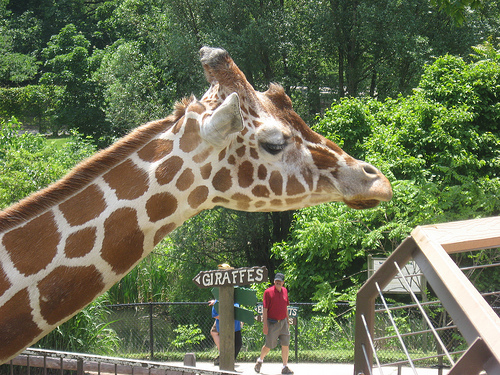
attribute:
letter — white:
[202, 267, 235, 292]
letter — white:
[210, 268, 229, 295]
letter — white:
[209, 261, 246, 291]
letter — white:
[228, 267, 252, 300]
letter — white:
[240, 259, 275, 287]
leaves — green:
[54, 24, 497, 284]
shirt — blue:
[211, 287, 243, 322]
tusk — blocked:
[413, 357, 455, 361]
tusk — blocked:
[378, 348, 448, 356]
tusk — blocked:
[401, 320, 459, 326]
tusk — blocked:
[367, 316, 447, 326]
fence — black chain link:
[98, 301, 350, 366]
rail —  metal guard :
[106, 294, 364, 364]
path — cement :
[105, 340, 376, 372]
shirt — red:
[260, 284, 289, 321]